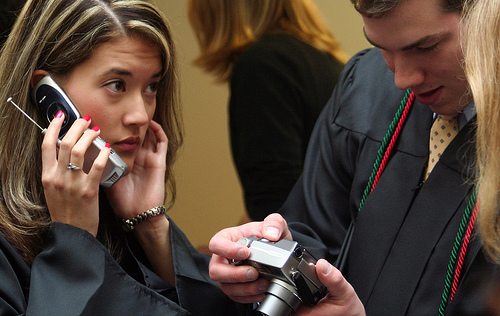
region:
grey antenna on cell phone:
[5, 90, 55, 137]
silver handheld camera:
[215, 228, 333, 313]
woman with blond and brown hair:
[12, 2, 184, 235]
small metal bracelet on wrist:
[115, 198, 174, 232]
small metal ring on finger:
[63, 151, 83, 179]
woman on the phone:
[13, 6, 185, 206]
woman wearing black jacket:
[188, 2, 353, 242]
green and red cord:
[360, 68, 422, 213]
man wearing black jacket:
[304, 0, 496, 262]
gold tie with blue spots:
[422, 110, 464, 170]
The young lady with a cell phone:
[0, 0, 232, 315]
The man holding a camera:
[209, 2, 499, 314]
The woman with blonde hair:
[186, 0, 351, 223]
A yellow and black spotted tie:
[422, 114, 463, 183]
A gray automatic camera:
[236, 237, 326, 314]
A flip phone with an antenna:
[7, 79, 127, 190]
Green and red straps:
[357, 92, 479, 314]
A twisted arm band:
[122, 203, 169, 231]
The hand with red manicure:
[44, 107, 111, 239]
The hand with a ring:
[67, 161, 82, 176]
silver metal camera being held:
[207, 213, 341, 314]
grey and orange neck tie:
[426, 107, 466, 177]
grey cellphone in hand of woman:
[3, 64, 157, 205]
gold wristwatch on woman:
[118, 192, 174, 244]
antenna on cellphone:
[1, 93, 49, 138]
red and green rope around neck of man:
[439, 223, 476, 287]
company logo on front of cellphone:
[32, 86, 61, 104]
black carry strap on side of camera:
[291, 268, 320, 310]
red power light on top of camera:
[241, 240, 258, 252]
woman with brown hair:
[191, 0, 336, 89]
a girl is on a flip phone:
[0, 0, 172, 217]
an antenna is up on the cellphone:
[1, 81, 120, 198]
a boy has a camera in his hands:
[221, 208, 338, 315]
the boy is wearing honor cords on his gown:
[306, 4, 493, 306]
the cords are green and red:
[336, 85, 486, 310]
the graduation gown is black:
[280, 45, 497, 307]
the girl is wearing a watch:
[120, 203, 171, 236]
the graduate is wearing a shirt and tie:
[423, 105, 481, 173]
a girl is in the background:
[183, 0, 353, 240]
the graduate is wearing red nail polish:
[42, 107, 112, 167]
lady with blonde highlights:
[0, 0, 201, 315]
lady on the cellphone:
[1, 1, 193, 314]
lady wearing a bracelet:
[1, 0, 199, 312]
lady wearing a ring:
[1, 0, 209, 315]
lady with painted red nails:
[0, 0, 210, 315]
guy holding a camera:
[202, 0, 494, 315]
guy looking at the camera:
[203, 3, 498, 314]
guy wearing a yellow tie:
[205, 0, 492, 312]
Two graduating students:
[0, 0, 496, 313]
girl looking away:
[1, 1, 186, 314]